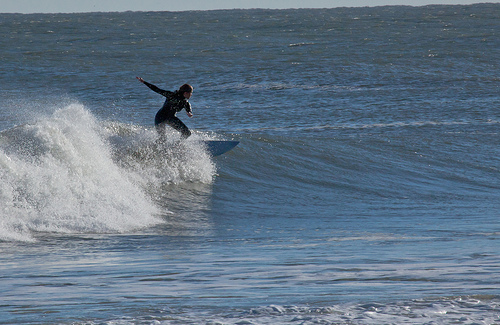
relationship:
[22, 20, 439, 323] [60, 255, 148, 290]
water has ripples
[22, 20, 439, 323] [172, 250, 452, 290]
water has ripples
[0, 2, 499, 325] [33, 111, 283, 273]
water has ripples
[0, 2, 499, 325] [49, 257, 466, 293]
water has ripples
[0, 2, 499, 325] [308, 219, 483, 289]
water has ripples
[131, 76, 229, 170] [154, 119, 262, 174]
woman on surfboard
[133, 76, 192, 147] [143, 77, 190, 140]
woman wearing a wetsuit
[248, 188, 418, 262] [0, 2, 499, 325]
ripples in water